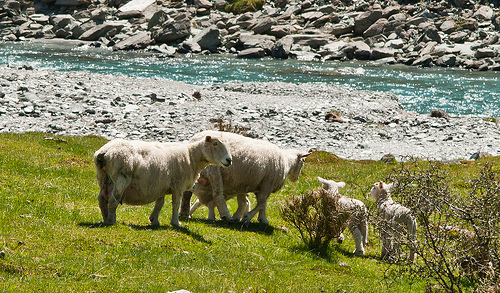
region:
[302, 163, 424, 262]
the wo small calf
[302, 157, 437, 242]
the calf is white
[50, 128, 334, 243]
the sheep are white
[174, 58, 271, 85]
the water is blue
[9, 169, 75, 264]
the grass is green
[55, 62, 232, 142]
the rocks are gray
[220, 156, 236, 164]
the sheep's nose is black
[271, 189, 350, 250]
the bush is brown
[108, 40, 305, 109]
the water is shallow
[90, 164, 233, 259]
the sheep has four feet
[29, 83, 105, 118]
WHITE ROCK ALONG RIVER BED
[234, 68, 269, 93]
BLUE WATER ALONG RIVER BANK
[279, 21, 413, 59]
LARGE GRAY RIVER ROCKS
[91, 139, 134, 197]
REAR END OF A SHEEP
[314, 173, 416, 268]
TWO BABY SHEEP IN GRASS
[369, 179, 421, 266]
BABY SHEEP BEHIND BRUSH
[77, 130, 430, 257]
FAMILY OF SHEEP IN GRASS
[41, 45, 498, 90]
FLOWING RIVER AND BOTH BANKS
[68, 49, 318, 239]
SHEEP HEADING TO RIVER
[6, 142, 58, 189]
GREEN AND GOLDEN GRASS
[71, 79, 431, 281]
family of 4 sheep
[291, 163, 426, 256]
two small baby lambs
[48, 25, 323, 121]
bright blue flowing water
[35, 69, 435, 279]
family of 5 sheep three babies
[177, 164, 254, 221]
baby lamb behind parent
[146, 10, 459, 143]
rocks near running water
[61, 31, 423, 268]
sheep out for grass and water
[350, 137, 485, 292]
unbloomed trees and bushes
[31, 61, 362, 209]
rocky beach behind family of sheep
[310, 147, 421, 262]
baby sheep in grass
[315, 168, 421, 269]
two lambs joining their mothers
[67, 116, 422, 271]
sheep heading towards water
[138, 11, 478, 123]
creek bank covered in rocks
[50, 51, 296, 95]
blue creek water flowing through pasture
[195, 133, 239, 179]
mother sheep looking at lambs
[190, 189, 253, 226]
lamb hiding behind mother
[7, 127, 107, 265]
green grass in sheep pasture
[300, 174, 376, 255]
lamb behind a bush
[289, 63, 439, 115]
water sparkling in sunlight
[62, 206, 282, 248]
shadows of sheep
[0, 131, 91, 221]
short green grass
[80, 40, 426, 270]
four sheep next to a river bank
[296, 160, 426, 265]
two young sheep behind a shrub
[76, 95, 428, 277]
two adult sheep guarding two young sheep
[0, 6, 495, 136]
river bank comprised of rocks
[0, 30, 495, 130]
river with light blue water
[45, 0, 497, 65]
hundreds of large rocks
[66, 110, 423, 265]
grey and white sheep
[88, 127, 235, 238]
black spots on a sheep's legs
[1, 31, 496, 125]
river with a weak current